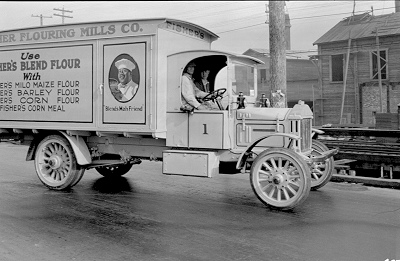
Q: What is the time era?
A: Vintage.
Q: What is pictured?
A: Truck.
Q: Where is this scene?
A: Street.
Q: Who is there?
A: Truck riders.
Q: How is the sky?
A: Overcast.